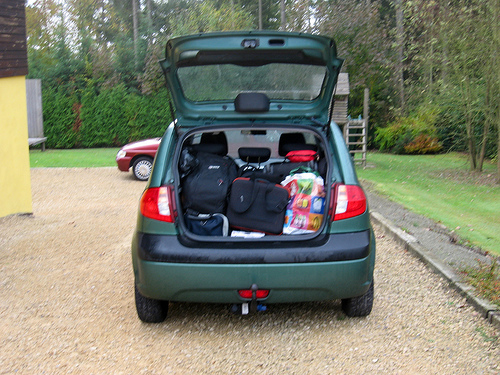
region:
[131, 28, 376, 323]
a green car parked in the driveway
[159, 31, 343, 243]
open trunk on the car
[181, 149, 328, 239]
luggage piled in the car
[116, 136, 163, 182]
a red car in the driveway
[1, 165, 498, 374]
a gravel driveway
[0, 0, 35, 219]
a yellow building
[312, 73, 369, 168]
a playhouse on the lawn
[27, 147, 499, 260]
a green, grassy area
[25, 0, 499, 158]
a wooded area behind the cars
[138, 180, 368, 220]
taillights on the car